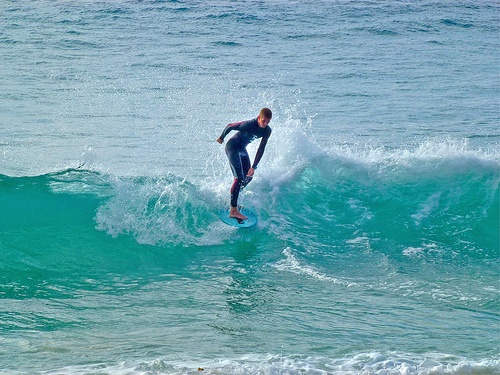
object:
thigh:
[225, 146, 247, 185]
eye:
[262, 119, 266, 122]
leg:
[225, 148, 247, 208]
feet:
[225, 209, 249, 222]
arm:
[220, 122, 245, 140]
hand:
[212, 135, 224, 146]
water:
[0, 0, 500, 374]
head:
[255, 107, 270, 129]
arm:
[250, 127, 274, 168]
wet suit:
[217, 118, 274, 210]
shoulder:
[238, 119, 254, 131]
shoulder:
[263, 124, 276, 138]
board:
[210, 201, 259, 229]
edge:
[217, 213, 244, 228]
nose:
[265, 121, 270, 128]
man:
[214, 107, 275, 222]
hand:
[244, 165, 257, 175]